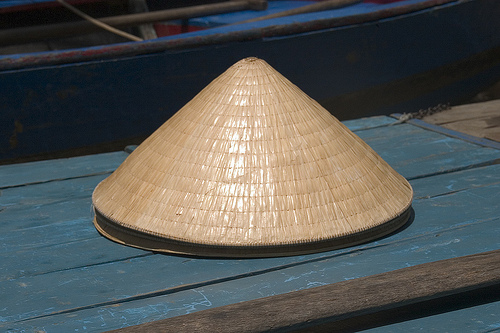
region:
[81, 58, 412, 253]
A hat on a wooden board.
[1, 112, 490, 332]
wooden board sits outside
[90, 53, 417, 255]
A brown hat sits outdoors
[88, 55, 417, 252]
A hat with a cone shape.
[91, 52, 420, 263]
Hat made a shiny surface.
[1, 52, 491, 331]
A wooden board is blue.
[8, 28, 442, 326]
this is a straw hat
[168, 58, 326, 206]
the hat is light brown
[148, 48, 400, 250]
the hat is straw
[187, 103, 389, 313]
the hat is light brown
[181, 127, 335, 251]
the hat is tan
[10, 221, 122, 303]
the table is painted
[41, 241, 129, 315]
the table is wooden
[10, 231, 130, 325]
the table is turqoise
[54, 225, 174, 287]
the paint is fading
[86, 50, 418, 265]
pair of conical bamboo hats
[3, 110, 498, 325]
blue wooden table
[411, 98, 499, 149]
section of natural wood in table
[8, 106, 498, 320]
blue slatted outdoor table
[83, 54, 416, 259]
two tan colored pointed hats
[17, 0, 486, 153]
blue row boat in the background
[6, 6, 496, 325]
Asian hat and boat scene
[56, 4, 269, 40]
brown wooden oars resting in boat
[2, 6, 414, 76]
blue edge of rown boat with red paint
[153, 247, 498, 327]
natural wood brown edge of blue table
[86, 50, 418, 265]
brown conical bamboo hats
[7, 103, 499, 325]
wooden turquoise slab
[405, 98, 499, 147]
edge of brown wooden table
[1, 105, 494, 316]
blue wooden table made with slats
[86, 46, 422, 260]
An upside down cone shaped object.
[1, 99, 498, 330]
A wooden table.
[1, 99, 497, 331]
A wooden object with some slats pained teal.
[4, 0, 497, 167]
A boat.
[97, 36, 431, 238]
A yellow hat thing.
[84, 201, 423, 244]
A yellow hat thing.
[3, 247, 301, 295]
A blue plank of wood.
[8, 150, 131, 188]
A blue plank of wood.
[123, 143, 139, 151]
A blue plank of wood.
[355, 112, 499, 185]
A blue plank of wood.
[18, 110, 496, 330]
A blue plank of wood.